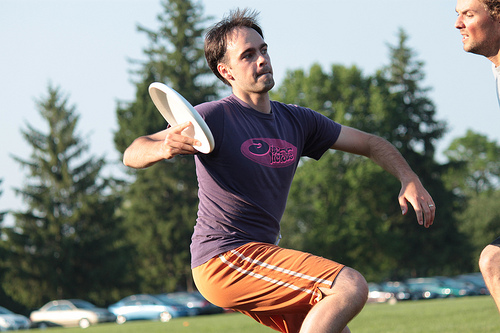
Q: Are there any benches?
A: No, there are no benches.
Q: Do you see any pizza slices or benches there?
A: No, there are no benches or pizza slices.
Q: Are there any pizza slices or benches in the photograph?
A: No, there are no benches or pizza slices.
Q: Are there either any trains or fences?
A: No, there are no fences or trains.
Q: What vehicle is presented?
A: The vehicle is a car.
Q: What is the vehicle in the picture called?
A: The vehicle is a car.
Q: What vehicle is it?
A: The vehicle is a car.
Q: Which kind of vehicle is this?
A: That is a car.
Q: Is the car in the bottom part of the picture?
A: Yes, the car is in the bottom of the image.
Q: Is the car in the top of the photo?
A: No, the car is in the bottom of the image.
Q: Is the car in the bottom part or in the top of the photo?
A: The car is in the bottom of the image.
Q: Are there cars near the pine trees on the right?
A: Yes, there is a car near the pine trees.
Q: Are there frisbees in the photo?
A: Yes, there is a frisbee.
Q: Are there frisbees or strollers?
A: Yes, there is a frisbee.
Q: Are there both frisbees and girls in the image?
A: No, there is a frisbee but no girls.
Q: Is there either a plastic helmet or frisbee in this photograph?
A: Yes, there is a plastic frisbee.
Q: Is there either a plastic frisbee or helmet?
A: Yes, there is a plastic frisbee.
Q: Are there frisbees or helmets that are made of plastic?
A: Yes, the frisbee is made of plastic.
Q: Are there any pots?
A: No, there are no pots.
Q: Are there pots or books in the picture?
A: No, there are no pots or books.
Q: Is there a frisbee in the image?
A: Yes, there is a frisbee.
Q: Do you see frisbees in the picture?
A: Yes, there is a frisbee.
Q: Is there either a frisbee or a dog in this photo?
A: Yes, there is a frisbee.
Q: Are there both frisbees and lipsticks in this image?
A: No, there is a frisbee but no lipsticks.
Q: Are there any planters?
A: No, there are no planters.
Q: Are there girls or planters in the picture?
A: No, there are no planters or girls.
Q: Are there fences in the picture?
A: No, there are no fences.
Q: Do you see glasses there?
A: No, there are no glasses.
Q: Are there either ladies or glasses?
A: No, there are no glasses or ladies.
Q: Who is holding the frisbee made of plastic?
A: The man is holding the frisbee.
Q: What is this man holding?
A: The man is holding the frisbee.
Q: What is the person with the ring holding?
A: The man is holding the frisbee.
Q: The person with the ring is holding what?
A: The man is holding the frisbee.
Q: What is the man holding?
A: The man is holding the frisbee.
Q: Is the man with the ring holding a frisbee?
A: Yes, the man is holding a frisbee.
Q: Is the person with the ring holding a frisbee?
A: Yes, the man is holding a frisbee.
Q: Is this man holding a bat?
A: No, the man is holding a frisbee.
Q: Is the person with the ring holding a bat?
A: No, the man is holding a frisbee.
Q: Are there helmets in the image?
A: No, there are no helmets.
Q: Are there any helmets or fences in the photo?
A: No, there are no helmets or fences.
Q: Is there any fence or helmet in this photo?
A: No, there are no helmets or fences.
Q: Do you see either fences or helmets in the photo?
A: No, there are no helmets or fences.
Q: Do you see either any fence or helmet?
A: No, there are no helmets or fences.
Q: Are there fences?
A: No, there are no fences.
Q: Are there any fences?
A: No, there are no fences.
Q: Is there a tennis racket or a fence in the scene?
A: No, there are no fences or rackets.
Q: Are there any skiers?
A: No, there are no skiers.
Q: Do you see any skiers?
A: No, there are no skiers.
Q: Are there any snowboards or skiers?
A: No, there are no skiers or snowboards.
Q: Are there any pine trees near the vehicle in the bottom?
A: Yes, there are pine trees near the car.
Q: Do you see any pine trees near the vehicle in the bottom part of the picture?
A: Yes, there are pine trees near the car.